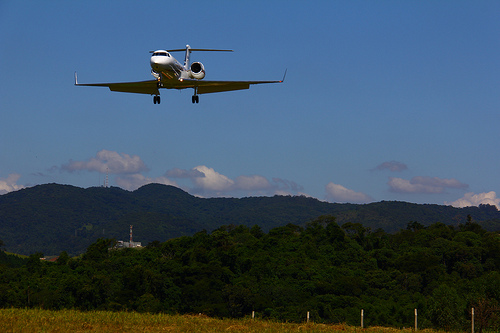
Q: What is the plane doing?
A: Flying.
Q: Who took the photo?
A: Someone on the ground.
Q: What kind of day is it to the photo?
A: Sunny.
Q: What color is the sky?
A: Blue.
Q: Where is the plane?
A: Flying.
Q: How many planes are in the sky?
A: One.